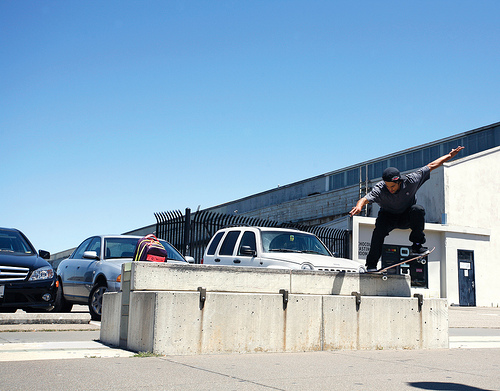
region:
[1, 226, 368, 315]
Vehicles that are parked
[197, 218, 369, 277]
A white jeep.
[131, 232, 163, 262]
Part of a backpack.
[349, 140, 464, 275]
A man on a skateboard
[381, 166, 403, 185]
A black cap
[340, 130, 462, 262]
A man with his arms out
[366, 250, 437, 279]
A skateboard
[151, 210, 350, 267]
A tall black metal fence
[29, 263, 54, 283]
A headlight on a car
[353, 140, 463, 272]
A man doing a trick on a skateboard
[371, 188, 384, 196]
man wearing grey shirt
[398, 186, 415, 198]
white symbol on shirt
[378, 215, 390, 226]
man wearing black pants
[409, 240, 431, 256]
man wearing black sneakers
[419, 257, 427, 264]
right wheel on board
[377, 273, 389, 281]
left wheel on board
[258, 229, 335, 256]
window of white van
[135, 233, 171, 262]
tricolor bag with handle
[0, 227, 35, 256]
window of black car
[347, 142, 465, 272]
a man performing a skateboard gring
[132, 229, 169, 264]
a red, tan, and brown backpack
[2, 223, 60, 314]
a parked black car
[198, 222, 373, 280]
a parked white jeep liberty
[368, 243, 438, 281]
a skateboard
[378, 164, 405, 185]
a hat on a man skateboarding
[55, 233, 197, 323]
a parked white car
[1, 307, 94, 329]
a grey concrete block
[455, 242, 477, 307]
a black metal door with a sign on it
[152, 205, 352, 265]
a black metal fence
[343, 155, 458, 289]
person skate boarding on a concrete slab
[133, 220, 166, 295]
black and neon back pack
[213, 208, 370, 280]
white jeep behind concrete barrier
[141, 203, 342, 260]
black fence behind vehicles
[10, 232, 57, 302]
black car to the left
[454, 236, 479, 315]
black door on side of a building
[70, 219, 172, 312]
silver car in middle of cars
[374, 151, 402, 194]
black hat worn by skater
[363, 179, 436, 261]
skater wearing black jeans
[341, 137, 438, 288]
young man doing tricks on skagteboard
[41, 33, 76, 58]
white clouds in blue sky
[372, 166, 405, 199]
the head of a man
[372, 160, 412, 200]
Hat on the guy's head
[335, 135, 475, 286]
A skateboarder is performing a trick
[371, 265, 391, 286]
White wheel of a skateboard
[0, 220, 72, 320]
A car is black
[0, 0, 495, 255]
A clear and blue sky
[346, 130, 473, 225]
Skateboarder has two arms raised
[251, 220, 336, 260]
Front window of a vehicle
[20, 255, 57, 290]
A headlight of a car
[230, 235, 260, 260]
A black side mirror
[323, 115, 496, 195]
Windows on a building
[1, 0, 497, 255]
A blue clear sky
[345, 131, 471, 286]
A skateboarder performing a trick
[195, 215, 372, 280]
A vehicle is white